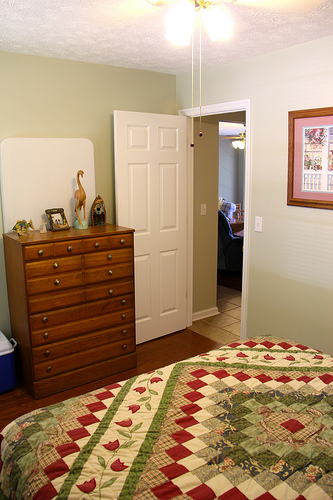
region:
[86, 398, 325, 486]
Patch work quilt bead spread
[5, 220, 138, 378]
Chest of drawers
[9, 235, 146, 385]
Wooden dresser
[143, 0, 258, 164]
Ceiling fan with lamps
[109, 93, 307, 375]
Open bedroom door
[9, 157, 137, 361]
Dresser with dinosaur models on top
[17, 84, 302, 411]
Simple American bedroom decor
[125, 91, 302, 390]
Man sitting in the other room reading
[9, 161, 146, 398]
Wooden chest of drawers with brass knobs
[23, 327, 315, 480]
Edge of bed with green and red quilted bed spread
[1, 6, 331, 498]
A small bedroom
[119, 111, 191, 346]
An open white bedroom door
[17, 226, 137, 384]
A wooden chest of drawers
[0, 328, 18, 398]
A blue cooler with a white lid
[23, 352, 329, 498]
A quilt with red flowers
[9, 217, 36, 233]
A fish figurine on the top of the chest of drawers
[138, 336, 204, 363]
A brown wooden floor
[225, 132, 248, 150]
A ceiling fan with light fixtures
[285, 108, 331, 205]
A picture with a pink matte and wooden frame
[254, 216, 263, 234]
A white light switch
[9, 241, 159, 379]
a wood dresser with brass handles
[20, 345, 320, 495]
a colorful quilt on the bed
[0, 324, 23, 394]
a blue plastic box with a white lid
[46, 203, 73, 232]
a golden frame on the dresser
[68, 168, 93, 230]
a figurine on the dresser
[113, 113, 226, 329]
an opened white door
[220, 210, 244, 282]
a blue armchair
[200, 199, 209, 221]
a white light switch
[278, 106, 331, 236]
a wood frame on the white wall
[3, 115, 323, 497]
a bedroom with a dresser and a bed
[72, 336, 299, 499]
flowered quilt on bed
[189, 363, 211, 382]
red patch on a quilt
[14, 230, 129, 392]
brown dresser with silver knobs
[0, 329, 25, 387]
blue and white cooler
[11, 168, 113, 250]
knick knacks on top of dresser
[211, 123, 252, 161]
light and ceiling fan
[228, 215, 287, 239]
light switch on wall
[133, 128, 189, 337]
tall white door with rectangle shapes on it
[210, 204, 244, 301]
blue recliner in room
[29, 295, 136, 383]
drawers on a dresser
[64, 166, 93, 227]
decorative bird sitting on dress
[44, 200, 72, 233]
wooden picture frame holding a picture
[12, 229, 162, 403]
wooden dress with lot of drawers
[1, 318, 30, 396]
blue cooler with white lid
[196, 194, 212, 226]
white face plate to light switch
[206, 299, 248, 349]
beige tile flooring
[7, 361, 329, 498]
Quilt of top of bed with flower prints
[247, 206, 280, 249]
white face plate for light switch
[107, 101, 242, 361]
white wooden bedroom door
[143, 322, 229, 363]
hard wood floor